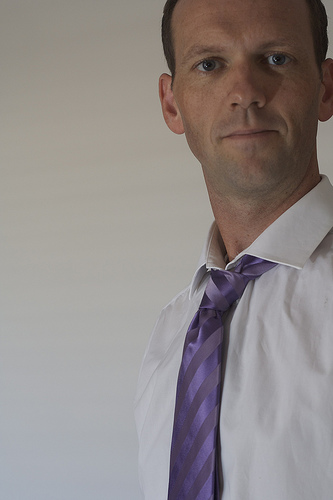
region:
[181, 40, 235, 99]
eye of a man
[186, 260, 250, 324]
knot of the tie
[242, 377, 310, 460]
white shirt on man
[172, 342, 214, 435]
pattern on the tie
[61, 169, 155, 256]
wall behind the man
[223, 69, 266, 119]
nose of the man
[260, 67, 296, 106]
shadow on man's face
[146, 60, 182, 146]
ear of the man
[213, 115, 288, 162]
mouth of the man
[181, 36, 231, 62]
eyebrow on the man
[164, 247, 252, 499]
purple striped tie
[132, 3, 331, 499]
man wearing white shirt and tie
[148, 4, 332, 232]
man looking at camera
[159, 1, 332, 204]
man with receding hairline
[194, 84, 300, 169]
wrinkles around man's mouth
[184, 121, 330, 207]
stubble on man's chin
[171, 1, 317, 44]
shallow wrinkles on man's forehead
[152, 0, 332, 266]
head turned toward camera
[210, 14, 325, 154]
shadow from man's nose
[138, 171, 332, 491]
white shirt with collar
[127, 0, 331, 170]
a man looking at the camera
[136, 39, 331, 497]
a man wearing a white t-shirt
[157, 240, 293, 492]
the man's purple striped silk tie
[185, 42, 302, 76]
the man's blue eyes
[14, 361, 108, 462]
white background of the picture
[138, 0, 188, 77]
the man's short black hair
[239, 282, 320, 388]
wrinkles in the man's t-shirt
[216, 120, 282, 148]
the man's thin lips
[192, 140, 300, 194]
grey skin of the man's chin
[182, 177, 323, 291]
white collar of the man's shirt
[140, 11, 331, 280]
this is a man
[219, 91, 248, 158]
the man is light skinned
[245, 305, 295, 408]
this is a shirt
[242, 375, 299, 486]
the shirt is white in color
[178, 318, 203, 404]
this is a tie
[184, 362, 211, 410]
the tie is blue in color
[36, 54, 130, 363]
this is the wall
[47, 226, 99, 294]
the wall is white in color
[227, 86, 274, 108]
this is the nose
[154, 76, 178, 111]
this is the ear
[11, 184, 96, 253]
this is the wall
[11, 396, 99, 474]
the wall is white in color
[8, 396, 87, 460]
the wall is clean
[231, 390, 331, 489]
this is a shirt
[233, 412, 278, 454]
the shirt is white in color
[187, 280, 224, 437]
this is a tie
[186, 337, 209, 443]
the tie is purple in color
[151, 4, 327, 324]
this is a man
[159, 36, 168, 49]
the hair is black in color